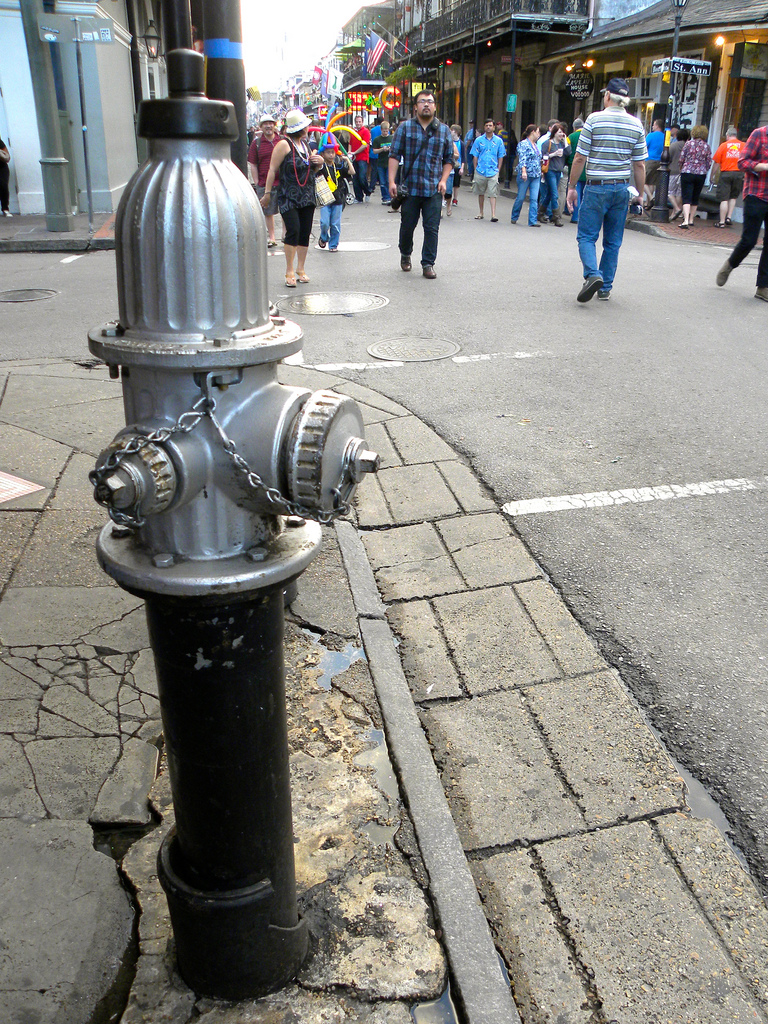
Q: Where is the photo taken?
A: On a walkway.